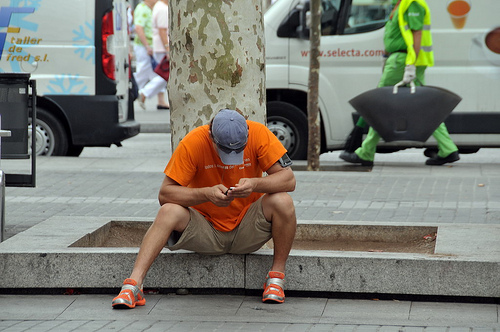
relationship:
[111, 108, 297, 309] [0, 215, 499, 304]
man sitting on curb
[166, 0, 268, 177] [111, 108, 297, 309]
tree trunk behind man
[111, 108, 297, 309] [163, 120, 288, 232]
man wearing shirt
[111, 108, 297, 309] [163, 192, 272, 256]
man wearing shorts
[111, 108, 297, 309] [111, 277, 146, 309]
man wearing shoe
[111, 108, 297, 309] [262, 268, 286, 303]
man wearing shoe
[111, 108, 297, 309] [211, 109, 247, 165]
man wearing cap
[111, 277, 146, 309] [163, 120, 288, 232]
shoe matches shirt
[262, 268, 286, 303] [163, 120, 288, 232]
shoe matches shirt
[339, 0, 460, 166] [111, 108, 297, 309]
man walking behind man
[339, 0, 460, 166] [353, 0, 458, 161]
man wearing clothing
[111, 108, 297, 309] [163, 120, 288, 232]
man has shirt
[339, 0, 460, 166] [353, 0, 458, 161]
man has clothing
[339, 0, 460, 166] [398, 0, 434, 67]
man has on vest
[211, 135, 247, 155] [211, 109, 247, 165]
sunglasses on cap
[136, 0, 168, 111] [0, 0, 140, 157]
passerby walking behind truck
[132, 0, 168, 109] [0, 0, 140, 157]
passerby walking behind truck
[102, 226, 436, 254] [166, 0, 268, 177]
dirt area for tree trunk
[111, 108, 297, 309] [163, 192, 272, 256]
man has shorts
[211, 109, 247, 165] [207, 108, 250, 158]
cap on man's head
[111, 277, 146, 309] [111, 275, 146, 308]
shoe on man's feet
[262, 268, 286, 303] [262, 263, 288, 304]
shoe on man's feet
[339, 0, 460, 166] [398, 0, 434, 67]
man wearing vest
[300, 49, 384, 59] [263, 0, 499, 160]
www.selecta.com on van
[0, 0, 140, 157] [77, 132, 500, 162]
truck beside road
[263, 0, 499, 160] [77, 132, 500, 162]
van beside road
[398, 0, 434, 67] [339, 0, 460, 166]
vest on man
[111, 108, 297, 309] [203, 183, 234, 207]
man looking down at hand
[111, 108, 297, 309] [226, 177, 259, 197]
man looking down at hand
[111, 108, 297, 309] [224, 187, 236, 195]
man holding cell phone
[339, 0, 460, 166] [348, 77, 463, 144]
man carrying bag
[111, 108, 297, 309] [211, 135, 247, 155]
man wearing sunglasses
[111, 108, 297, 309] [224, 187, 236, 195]
man on cell phone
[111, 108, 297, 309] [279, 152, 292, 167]
man wearing ipod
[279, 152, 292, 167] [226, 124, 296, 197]
ipod on arm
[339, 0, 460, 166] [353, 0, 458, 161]
man dressed in clothing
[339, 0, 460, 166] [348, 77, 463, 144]
man holding bag